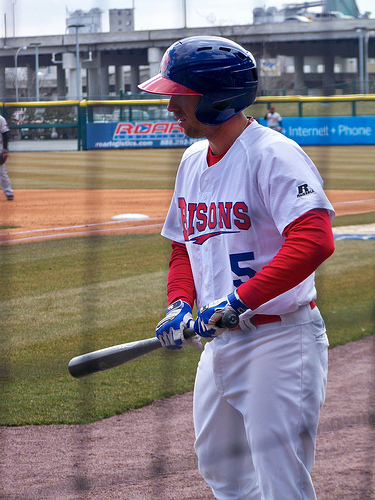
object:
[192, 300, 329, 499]
pants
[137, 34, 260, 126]
helmet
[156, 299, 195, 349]
glove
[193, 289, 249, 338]
glove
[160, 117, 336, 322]
shirt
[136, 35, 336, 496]
person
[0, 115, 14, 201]
person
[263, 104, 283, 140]
person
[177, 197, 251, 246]
bisons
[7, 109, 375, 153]
fence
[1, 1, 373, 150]
background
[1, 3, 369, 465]
outfield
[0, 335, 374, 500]
dirt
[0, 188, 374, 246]
dirt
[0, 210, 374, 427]
grass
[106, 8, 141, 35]
building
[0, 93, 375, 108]
fence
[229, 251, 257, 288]
number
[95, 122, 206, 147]
advertisement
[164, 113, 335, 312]
undershirt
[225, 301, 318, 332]
belt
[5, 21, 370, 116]
deck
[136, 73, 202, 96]
part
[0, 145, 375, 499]
ground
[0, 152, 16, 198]
part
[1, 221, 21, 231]
part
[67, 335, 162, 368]
edge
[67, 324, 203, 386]
club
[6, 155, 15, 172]
part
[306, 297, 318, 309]
part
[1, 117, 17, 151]
part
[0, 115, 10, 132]
part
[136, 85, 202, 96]
edge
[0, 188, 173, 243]
box